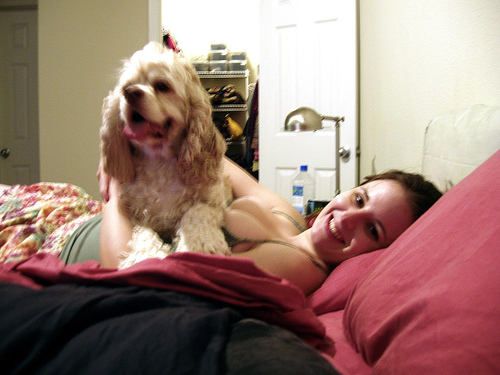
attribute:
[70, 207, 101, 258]
tank top — gray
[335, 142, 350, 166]
knob — door, silver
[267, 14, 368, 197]
door — closet, white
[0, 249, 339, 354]
sheets — pink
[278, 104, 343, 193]
lamp — silver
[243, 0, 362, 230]
door — white